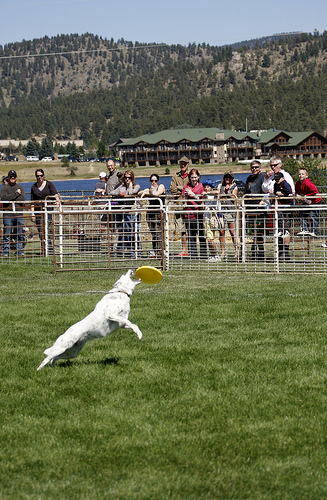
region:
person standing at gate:
[28, 159, 63, 237]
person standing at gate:
[145, 170, 166, 237]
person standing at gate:
[294, 169, 321, 236]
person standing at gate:
[219, 165, 238, 229]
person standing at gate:
[178, 165, 203, 229]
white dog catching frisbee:
[25, 255, 168, 398]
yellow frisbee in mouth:
[122, 253, 164, 286]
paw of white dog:
[134, 329, 150, 342]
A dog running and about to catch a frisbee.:
[25, 261, 175, 385]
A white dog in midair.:
[30, 267, 143, 370]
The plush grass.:
[0, 239, 325, 498]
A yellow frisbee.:
[134, 265, 162, 283]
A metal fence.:
[0, 195, 326, 273]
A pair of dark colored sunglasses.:
[249, 165, 260, 169]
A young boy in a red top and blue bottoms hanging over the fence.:
[295, 168, 322, 239]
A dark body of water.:
[1, 172, 326, 208]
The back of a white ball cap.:
[97, 171, 108, 178]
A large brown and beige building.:
[112, 124, 326, 167]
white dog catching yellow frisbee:
[28, 257, 166, 368]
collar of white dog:
[112, 285, 139, 302]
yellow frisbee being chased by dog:
[132, 263, 165, 285]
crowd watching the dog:
[3, 144, 318, 259]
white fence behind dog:
[0, 192, 322, 279]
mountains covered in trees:
[3, 30, 324, 142]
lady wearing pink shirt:
[180, 167, 206, 258]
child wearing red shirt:
[294, 171, 321, 238]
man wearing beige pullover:
[166, 155, 192, 256]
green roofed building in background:
[106, 122, 324, 159]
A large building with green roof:
[108, 128, 325, 167]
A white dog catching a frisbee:
[36, 268, 142, 371]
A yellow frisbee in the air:
[135, 265, 163, 284]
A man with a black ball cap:
[0, 170, 26, 257]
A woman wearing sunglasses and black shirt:
[31, 168, 60, 254]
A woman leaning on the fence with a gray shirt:
[108, 171, 142, 256]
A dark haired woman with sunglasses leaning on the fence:
[137, 174, 164, 258]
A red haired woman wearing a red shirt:
[180, 168, 207, 260]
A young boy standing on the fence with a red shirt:
[294, 169, 321, 238]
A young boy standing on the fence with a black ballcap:
[271, 171, 291, 238]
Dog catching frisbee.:
[33, 265, 168, 372]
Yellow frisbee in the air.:
[131, 264, 163, 283]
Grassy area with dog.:
[5, 237, 324, 498]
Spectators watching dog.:
[3, 157, 325, 261]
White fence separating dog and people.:
[2, 192, 325, 274]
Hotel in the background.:
[109, 123, 326, 166]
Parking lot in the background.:
[0, 151, 110, 167]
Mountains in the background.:
[1, 28, 325, 150]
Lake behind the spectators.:
[7, 167, 286, 199]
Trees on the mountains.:
[2, 27, 326, 156]